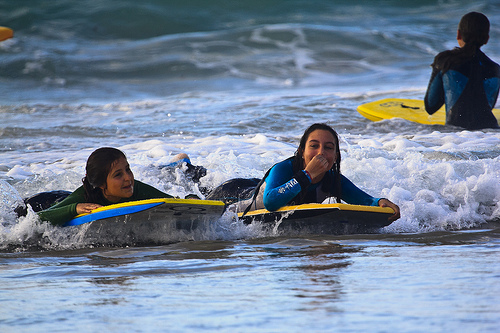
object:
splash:
[0, 209, 385, 252]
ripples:
[429, 147, 499, 168]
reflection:
[256, 235, 370, 320]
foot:
[164, 152, 191, 164]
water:
[0, 1, 498, 332]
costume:
[422, 44, 499, 131]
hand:
[375, 197, 402, 222]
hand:
[75, 202, 103, 215]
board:
[60, 197, 229, 229]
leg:
[177, 163, 212, 199]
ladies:
[10, 147, 201, 228]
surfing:
[12, 145, 231, 230]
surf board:
[354, 97, 499, 126]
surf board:
[234, 201, 395, 227]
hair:
[80, 146, 128, 208]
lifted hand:
[300, 152, 329, 177]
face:
[303, 127, 337, 174]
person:
[421, 11, 499, 133]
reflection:
[68, 235, 235, 305]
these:
[13, 122, 402, 221]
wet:
[13, 189, 72, 222]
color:
[109, 179, 122, 188]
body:
[152, 152, 400, 222]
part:
[123, 240, 315, 328]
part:
[395, 240, 499, 319]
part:
[19, 250, 61, 289]